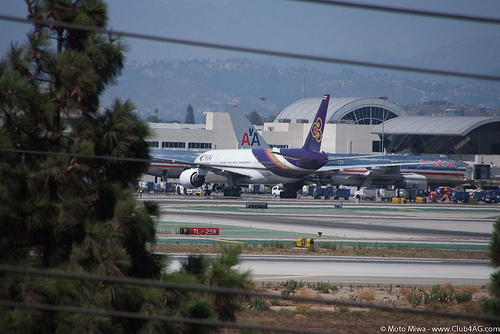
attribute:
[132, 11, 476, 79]
sky — hazy, clear, grey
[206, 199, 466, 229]
runway — concrete, Airport Runway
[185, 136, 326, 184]
plane — parked, waiting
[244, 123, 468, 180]
plane — airlines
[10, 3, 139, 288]
tree — pine, green, tall, evergreen, growing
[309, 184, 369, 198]
luggage — loaded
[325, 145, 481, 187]
airplane — parked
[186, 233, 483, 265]
ground — dry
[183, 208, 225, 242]
sign — red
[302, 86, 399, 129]
window — curved, huge